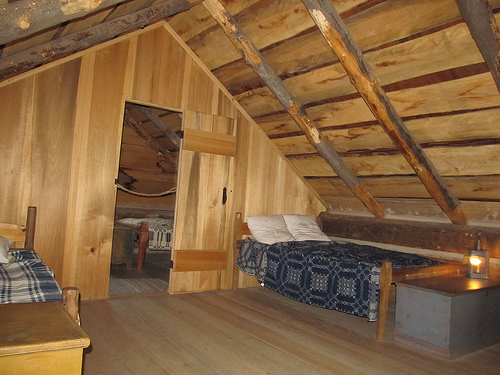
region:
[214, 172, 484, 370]
a bed that is inside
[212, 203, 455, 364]
a bed with pillows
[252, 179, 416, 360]
a bed with two pillows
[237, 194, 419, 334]
a bed with white pillows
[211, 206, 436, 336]
a bed with a balnket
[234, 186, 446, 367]
a small bed inside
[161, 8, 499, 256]
a roof that is slanted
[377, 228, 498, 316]
a table with a light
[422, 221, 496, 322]
a light turned on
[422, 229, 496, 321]
a light on the table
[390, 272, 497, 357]
a grey chest at the foot of a bed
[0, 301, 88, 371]
a brown wood chest at the foot of a bed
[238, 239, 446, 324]
a navy blue comforter on a bed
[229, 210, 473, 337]
a wooden bed frome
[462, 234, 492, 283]
a lamp on a gray chest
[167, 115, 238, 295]
a wooden door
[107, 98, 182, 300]
an open doorway into a room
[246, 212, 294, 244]
a white pillow on a bed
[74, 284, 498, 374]
a wooden floor in a room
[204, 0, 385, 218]
a log beam in the ceiling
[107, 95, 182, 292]
A doorway to a bedroom in a cabin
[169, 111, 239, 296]
A door to a bedroom in a cabin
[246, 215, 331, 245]
Two white pillows on a bed in a cabin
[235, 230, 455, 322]
A bed with two pillows on it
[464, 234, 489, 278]
Lantern at the foot of a bed on a desk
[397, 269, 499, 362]
A gray desk at the end of a bed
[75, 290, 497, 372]
A wood floor in a cabin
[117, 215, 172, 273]
A bed in an adjoining room with no pillows on top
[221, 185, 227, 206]
Door handle on wooden door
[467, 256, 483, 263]
A light inside a lantern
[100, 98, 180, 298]
doorway of the cabin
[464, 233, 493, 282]
bottle lamp that is lit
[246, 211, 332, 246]
a pair of white square pillows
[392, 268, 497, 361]
grey painted wood chest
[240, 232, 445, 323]
a patterned quilt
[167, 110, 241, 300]
a door of the cabin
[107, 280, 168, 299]
a rectangle area rug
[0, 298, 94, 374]
a natural wood chest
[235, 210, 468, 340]
a natural wood frame bed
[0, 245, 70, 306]
a grey and blue plaid bedspread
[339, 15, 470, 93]
wooden ceiling on roof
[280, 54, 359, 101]
wooden ceiling on roof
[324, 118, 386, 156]
wooden ceiling on roof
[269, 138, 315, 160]
wooden ceiling on roof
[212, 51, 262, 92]
wooden ceiling on roof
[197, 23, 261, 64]
wooden ceiling on roof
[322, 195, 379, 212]
wooden ceiling on roof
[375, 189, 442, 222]
wooden ceiling on roof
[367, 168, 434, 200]
wooden ceiling on roof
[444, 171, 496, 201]
wooden ceiling on roof